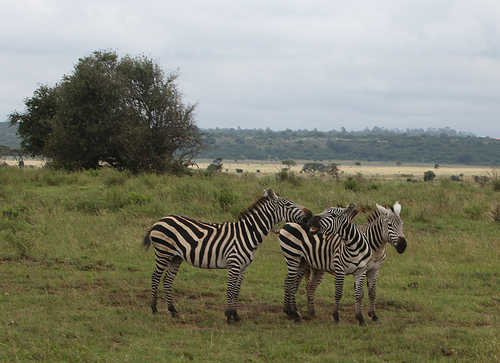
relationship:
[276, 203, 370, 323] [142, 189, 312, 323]
zebra play biting zebra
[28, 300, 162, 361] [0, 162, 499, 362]
grass covering ground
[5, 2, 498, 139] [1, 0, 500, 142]
clouds in overcast sky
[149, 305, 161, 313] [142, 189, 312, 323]
hoof(foot) on zebra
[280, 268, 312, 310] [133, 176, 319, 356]
foot on zebra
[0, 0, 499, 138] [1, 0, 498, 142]
clouds are in overcast sky